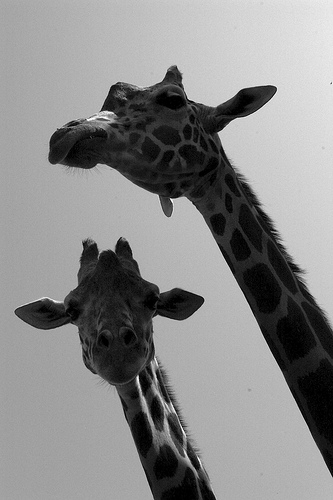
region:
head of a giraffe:
[38, 62, 230, 200]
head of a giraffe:
[34, 241, 198, 377]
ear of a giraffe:
[152, 278, 205, 338]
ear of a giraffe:
[13, 297, 76, 338]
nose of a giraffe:
[86, 321, 146, 356]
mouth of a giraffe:
[95, 348, 154, 392]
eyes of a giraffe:
[52, 274, 171, 319]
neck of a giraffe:
[108, 395, 226, 496]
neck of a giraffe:
[203, 203, 332, 379]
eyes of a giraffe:
[101, 81, 191, 113]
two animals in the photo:
[49, 67, 326, 490]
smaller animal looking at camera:
[50, 247, 180, 405]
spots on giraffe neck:
[130, 364, 190, 499]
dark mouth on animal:
[50, 127, 114, 185]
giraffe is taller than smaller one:
[101, 71, 332, 469]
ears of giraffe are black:
[201, 74, 277, 111]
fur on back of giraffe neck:
[153, 373, 202, 461]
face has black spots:
[76, 82, 209, 177]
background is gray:
[6, 381, 110, 493]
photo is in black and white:
[0, 44, 317, 488]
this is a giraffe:
[21, 69, 324, 436]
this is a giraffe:
[14, 224, 224, 492]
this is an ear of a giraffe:
[155, 276, 211, 335]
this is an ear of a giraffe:
[1, 289, 77, 351]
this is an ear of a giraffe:
[205, 73, 291, 137]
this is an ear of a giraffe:
[152, 188, 182, 226]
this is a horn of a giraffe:
[112, 228, 145, 266]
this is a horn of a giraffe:
[69, 231, 108, 269]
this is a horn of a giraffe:
[158, 60, 191, 89]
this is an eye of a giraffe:
[144, 280, 175, 320]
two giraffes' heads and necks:
[12, 65, 331, 499]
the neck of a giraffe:
[221, 164, 331, 454]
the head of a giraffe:
[48, 63, 278, 216]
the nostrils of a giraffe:
[96, 325, 139, 350]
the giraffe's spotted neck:
[117, 391, 218, 499]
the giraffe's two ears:
[13, 286, 205, 331]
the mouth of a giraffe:
[89, 357, 151, 388]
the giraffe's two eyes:
[63, 290, 160, 321]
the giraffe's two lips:
[46, 125, 108, 168]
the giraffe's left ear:
[199, 81, 284, 139]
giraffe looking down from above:
[10, 234, 207, 499]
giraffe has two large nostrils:
[91, 325, 141, 353]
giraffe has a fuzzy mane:
[220, 148, 331, 335]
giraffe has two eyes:
[59, 279, 166, 324]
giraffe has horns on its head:
[71, 236, 141, 285]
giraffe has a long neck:
[184, 164, 331, 497]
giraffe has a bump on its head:
[95, 246, 123, 286]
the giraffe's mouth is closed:
[43, 115, 112, 174]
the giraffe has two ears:
[13, 281, 216, 335]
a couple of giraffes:
[12, 49, 332, 494]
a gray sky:
[3, 7, 328, 497]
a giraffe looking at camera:
[2, 238, 253, 499]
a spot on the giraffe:
[128, 410, 158, 459]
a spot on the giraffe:
[163, 473, 187, 499]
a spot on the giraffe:
[147, 396, 166, 422]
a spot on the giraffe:
[162, 415, 186, 456]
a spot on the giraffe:
[271, 306, 307, 364]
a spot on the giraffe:
[295, 351, 332, 413]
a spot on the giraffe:
[239, 213, 263, 245]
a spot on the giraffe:
[270, 250, 296, 292]